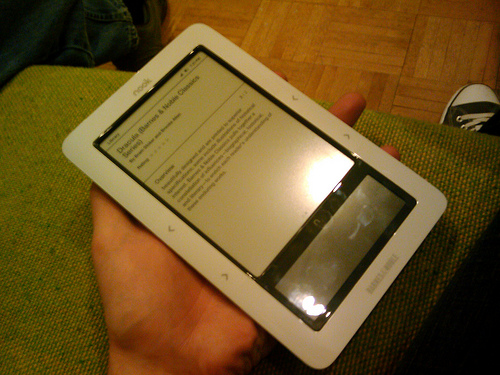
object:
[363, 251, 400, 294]
logo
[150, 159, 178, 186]
words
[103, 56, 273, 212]
text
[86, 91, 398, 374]
hand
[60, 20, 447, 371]
white border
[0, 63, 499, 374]
pillow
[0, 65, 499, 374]
cushion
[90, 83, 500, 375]
person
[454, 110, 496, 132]
laces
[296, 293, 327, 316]
glare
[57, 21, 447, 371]
electronic book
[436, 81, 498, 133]
converse shoe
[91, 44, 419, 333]
screen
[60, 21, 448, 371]
tablet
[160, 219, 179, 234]
button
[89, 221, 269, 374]
palm